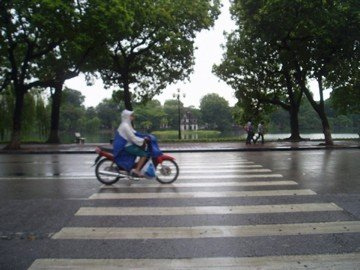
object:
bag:
[144, 162, 157, 181]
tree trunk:
[284, 87, 304, 143]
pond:
[238, 131, 360, 139]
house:
[179, 109, 201, 130]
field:
[141, 127, 246, 144]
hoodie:
[118, 109, 147, 148]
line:
[72, 202, 343, 217]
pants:
[125, 145, 148, 158]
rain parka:
[111, 109, 147, 174]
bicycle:
[90, 134, 180, 185]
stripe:
[87, 188, 319, 202]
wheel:
[94, 157, 120, 185]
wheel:
[152, 155, 181, 185]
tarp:
[134, 129, 163, 157]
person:
[111, 108, 150, 178]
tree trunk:
[47, 68, 69, 145]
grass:
[7, 136, 93, 143]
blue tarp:
[112, 132, 126, 158]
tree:
[210, 24, 313, 143]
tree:
[100, 19, 198, 142]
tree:
[22, 31, 96, 143]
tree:
[0, 0, 56, 151]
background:
[0, 0, 360, 269]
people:
[253, 120, 269, 144]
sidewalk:
[0, 138, 360, 155]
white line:
[24, 245, 359, 269]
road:
[1, 148, 360, 269]